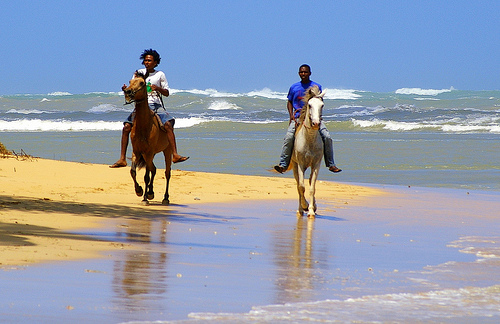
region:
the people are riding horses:
[92, 30, 354, 223]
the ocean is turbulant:
[201, 81, 263, 126]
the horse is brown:
[117, 75, 180, 196]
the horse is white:
[287, 92, 341, 209]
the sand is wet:
[204, 196, 264, 307]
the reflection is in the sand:
[272, 221, 322, 271]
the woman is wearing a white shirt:
[143, 68, 172, 100]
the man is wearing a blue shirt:
[280, 77, 302, 117]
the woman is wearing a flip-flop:
[171, 151, 192, 168]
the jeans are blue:
[274, 117, 295, 167]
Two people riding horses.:
[107, 43, 397, 220]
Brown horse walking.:
[122, 75, 172, 209]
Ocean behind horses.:
[10, 84, 498, 149]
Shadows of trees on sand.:
[0, 192, 246, 264]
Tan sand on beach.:
[0, 147, 108, 204]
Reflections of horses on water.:
[103, 198, 345, 307]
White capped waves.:
[328, 83, 495, 135]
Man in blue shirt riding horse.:
[275, 62, 340, 221]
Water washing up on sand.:
[183, 219, 497, 321]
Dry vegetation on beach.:
[0, 139, 40, 171]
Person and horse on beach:
[107, 48, 188, 203]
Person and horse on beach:
[274, 61, 341, 217]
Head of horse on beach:
[121, 70, 147, 107]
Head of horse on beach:
[306, 85, 326, 128]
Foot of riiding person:
[109, 159, 124, 169]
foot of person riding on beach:
[171, 152, 186, 161]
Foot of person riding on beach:
[268, 159, 289, 176]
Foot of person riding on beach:
[326, 159, 343, 178]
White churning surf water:
[15, 120, 66, 130]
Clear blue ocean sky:
[198, 22, 283, 47]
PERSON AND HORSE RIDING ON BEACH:
[109, 46, 189, 209]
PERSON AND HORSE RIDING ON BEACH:
[274, 62, 344, 216]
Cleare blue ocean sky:
[322, 29, 392, 49]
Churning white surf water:
[11, 117, 65, 130]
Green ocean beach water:
[368, 146, 454, 163]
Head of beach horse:
[306, 91, 329, 129]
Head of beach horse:
[121, 72, 148, 105]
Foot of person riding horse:
[105, 158, 125, 170]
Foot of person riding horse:
[170, 151, 189, 161]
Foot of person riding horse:
[271, 162, 286, 170]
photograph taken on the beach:
[15, 16, 497, 298]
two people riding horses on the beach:
[78, 21, 386, 234]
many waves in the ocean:
[27, 87, 487, 142]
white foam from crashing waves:
[11, 118, 98, 135]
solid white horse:
[283, 88, 338, 214]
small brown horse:
[109, 68, 175, 212]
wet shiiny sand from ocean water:
[107, 202, 434, 321]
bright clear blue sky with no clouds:
[44, 11, 453, 48]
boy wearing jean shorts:
[117, 39, 186, 135]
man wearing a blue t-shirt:
[275, 62, 333, 149]